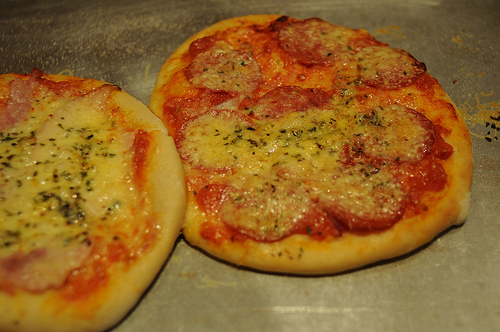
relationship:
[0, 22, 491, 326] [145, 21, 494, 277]
two pizzas showing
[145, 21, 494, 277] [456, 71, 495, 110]
pizza has crumbs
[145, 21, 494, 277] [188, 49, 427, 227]
pepperoni with cheese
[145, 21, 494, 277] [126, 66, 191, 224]
pizza has crust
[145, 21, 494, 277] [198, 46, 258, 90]
pizza has pepperoni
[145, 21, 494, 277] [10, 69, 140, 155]
pizza has ham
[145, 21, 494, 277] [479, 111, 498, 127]
pizza has black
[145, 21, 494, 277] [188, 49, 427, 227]
pizza has cheese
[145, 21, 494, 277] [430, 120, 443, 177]
pizza has sauce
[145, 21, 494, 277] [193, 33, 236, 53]
pizza has tomatoes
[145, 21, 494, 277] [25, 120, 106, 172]
pizza has herbs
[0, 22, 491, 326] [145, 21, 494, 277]
two pizzas shown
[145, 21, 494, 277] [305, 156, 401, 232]
pizza has canadian bacon